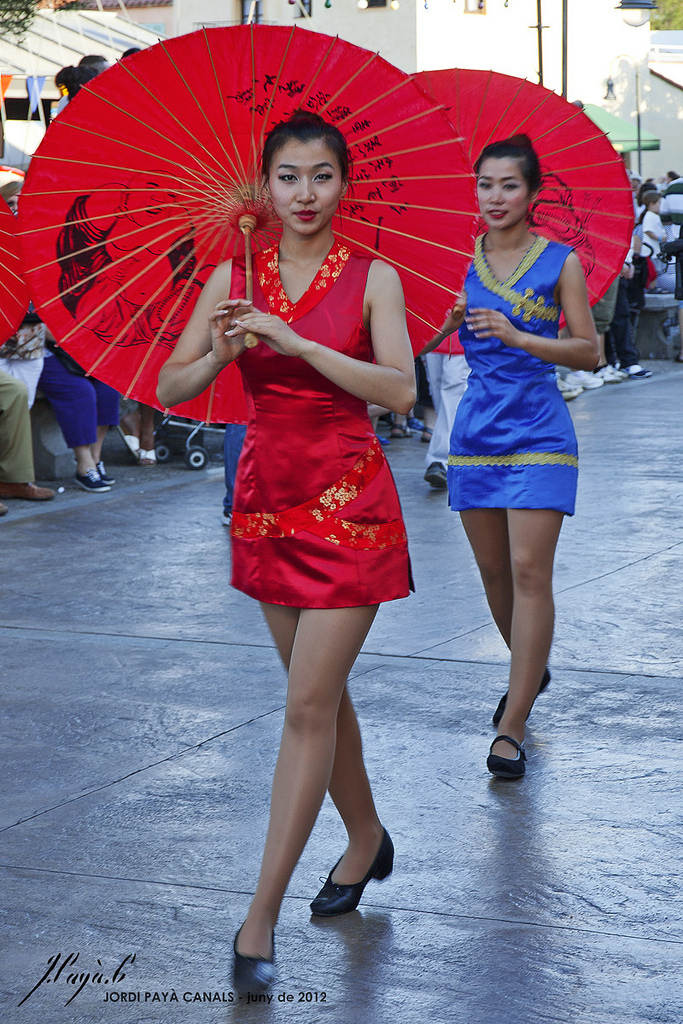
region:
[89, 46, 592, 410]
women hold red umbrellas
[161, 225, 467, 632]
woman has red dress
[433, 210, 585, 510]
blue and gold dress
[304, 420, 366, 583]
gold flowers on dress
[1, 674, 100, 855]
walkway is dark grey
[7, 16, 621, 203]
white buildings behind women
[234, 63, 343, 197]
woman has black hair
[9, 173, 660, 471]
people sitting behind women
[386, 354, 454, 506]
person walking behind women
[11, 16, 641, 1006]
TWO WOMEN HOLDING RED UMBRELLAS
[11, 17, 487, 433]
A RED UMBRELLA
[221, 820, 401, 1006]
A PAIR OF BLACK PUMPS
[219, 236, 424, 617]
A RED ASIAN DRESS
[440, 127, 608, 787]
A WOMAN WEARING A BLUE DRESS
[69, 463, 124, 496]
A PAIR OF SNEAKERS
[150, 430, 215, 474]
TWO CART WHEELS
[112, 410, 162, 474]
A PAIR OF WHITE SANDALS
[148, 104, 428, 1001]
A WOMAN WEARING A RED DRESS CARRYING AN UMBRELLA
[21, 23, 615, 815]
the women are walking with umbrellas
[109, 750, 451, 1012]
the shoes are black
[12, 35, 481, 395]
the umbrella is open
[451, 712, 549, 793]
the shoe has a strap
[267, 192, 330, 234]
the woman's lips are red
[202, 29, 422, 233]
writing on the umbrella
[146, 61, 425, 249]
the writing is in black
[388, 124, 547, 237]
the woman is smiling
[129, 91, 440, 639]
the woman in the front is wearing a red dress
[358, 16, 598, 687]
the woman in the back is wearing a blue dress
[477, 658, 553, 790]
black Mary-Jane style shoes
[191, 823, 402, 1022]
black ballet-slipper style shoes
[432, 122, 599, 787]
woman wearing blue dress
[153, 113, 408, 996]
woman wearing red dress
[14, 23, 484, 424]
red parasol with black lettering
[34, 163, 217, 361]
image of Buddha on parasol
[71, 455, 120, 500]
black sneakers with white laces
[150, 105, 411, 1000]
woman wearing hair in bun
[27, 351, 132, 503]
blue capri pants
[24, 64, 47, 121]
a blue pendant flag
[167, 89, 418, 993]
girl in the red dress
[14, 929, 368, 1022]
watermark on the picture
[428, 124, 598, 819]
girl in the blue dress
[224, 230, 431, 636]
red dress on the gril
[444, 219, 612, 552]
blue dress on the girl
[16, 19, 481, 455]
umbrella of the girl in red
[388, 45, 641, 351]
umbrella of the girl in blue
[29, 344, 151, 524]
blue pants on a person sitting down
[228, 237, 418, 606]
red silk Japanese dress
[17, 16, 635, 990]
two women with red umbrellas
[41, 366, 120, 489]
legs of an obese woman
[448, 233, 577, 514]
blue and gold short dress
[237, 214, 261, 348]
bamboo handle on an umbrella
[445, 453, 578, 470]
gold curvy trim on a dress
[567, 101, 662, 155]
green awning on a building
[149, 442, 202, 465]
wheels on the bottom of a cart or stroller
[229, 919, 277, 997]
the shoe is black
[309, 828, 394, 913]
the shoe is black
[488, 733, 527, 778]
the shoe is black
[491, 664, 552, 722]
the shoe is black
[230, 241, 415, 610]
the dress is red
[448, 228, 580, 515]
the dress is blue